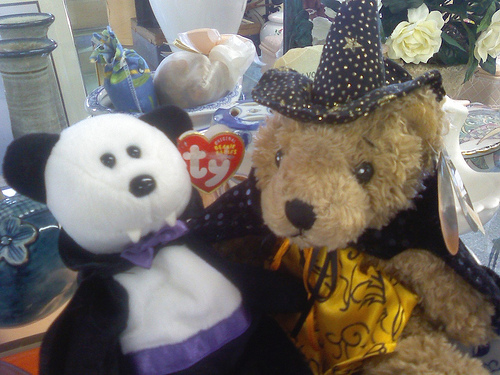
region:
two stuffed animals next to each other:
[35, 35, 480, 345]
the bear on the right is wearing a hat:
[246, 0, 441, 158]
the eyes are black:
[250, 136, 396, 192]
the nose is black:
[265, 195, 334, 243]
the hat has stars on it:
[297, 21, 388, 121]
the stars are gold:
[301, 11, 397, 97]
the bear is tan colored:
[221, 90, 449, 320]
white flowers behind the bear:
[390, 1, 498, 71]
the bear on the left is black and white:
[10, 93, 265, 343]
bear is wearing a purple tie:
[107, 207, 209, 274]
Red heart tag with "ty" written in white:
[175, 128, 250, 193]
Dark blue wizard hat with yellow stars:
[282, 3, 412, 121]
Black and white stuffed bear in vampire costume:
[13, 106, 241, 372]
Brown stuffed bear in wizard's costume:
[250, 3, 446, 350]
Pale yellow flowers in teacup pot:
[390, 6, 499, 81]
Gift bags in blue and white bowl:
[90, 24, 240, 120]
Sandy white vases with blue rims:
[0, 10, 53, 140]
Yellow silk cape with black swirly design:
[285, 251, 386, 357]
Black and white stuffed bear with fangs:
[50, 117, 184, 257]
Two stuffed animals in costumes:
[22, 62, 462, 367]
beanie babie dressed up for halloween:
[1, 91, 273, 361]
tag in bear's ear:
[168, 117, 246, 192]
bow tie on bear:
[136, 219, 185, 265]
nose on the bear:
[129, 176, 157, 201]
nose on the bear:
[287, 199, 317, 225]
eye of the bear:
[333, 145, 369, 189]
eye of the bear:
[271, 151, 290, 166]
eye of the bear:
[93, 153, 122, 175]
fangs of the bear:
[129, 215, 181, 238]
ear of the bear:
[6, 121, 62, 201]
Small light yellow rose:
[388, 8, 440, 63]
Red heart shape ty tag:
[178, 128, 243, 190]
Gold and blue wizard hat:
[253, 0, 447, 122]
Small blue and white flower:
[0, 215, 37, 267]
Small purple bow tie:
[125, 220, 190, 262]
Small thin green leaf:
[442, 32, 469, 54]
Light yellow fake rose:
[476, 8, 499, 61]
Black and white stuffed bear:
[7, 104, 309, 374]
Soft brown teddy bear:
[252, 7, 497, 374]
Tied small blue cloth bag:
[90, 28, 155, 110]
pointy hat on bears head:
[251, 0, 439, 120]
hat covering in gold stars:
[251, 0, 442, 122]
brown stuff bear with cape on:
[223, 88, 494, 373]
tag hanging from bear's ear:
[434, 146, 459, 256]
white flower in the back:
[383, 8, 442, 63]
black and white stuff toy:
[5, 105, 311, 373]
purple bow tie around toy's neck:
[123, 219, 187, 267]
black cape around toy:
[41, 186, 305, 371]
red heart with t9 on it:
[179, 131, 242, 191]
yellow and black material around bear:
[221, 233, 413, 373]